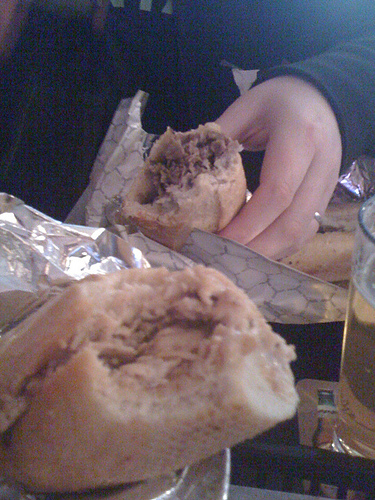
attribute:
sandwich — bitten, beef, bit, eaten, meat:
[28, 223, 332, 476]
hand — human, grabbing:
[108, 72, 251, 243]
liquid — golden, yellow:
[319, 239, 367, 444]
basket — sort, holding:
[228, 345, 348, 491]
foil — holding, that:
[27, 195, 104, 265]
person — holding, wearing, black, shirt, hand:
[108, 71, 331, 297]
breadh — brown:
[217, 377, 286, 443]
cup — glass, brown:
[301, 311, 371, 467]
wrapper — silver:
[3, 181, 134, 294]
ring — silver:
[300, 196, 340, 246]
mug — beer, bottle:
[282, 276, 373, 469]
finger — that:
[185, 140, 295, 297]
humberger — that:
[125, 119, 267, 254]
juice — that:
[298, 329, 368, 465]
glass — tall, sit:
[272, 234, 367, 450]